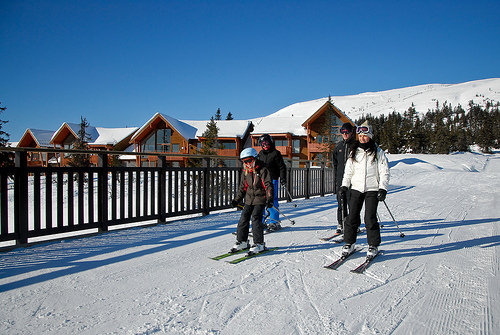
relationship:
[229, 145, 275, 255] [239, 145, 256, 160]
guy wearing blue helmet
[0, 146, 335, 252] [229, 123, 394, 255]
wooden fence beside skiers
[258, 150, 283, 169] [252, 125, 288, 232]
jacket on person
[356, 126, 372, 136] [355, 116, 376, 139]
goggles on hat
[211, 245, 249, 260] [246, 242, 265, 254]
green ski on foot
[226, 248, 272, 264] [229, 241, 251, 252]
green ski on foot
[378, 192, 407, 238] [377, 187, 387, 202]
pole in hand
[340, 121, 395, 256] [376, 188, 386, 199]
skiers wearing glove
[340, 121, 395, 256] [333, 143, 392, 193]
skiers wearing jacket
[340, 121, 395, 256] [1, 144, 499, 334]
skiers skating on snow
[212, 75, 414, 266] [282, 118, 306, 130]
roof covered with snow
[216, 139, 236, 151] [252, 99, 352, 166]
window of house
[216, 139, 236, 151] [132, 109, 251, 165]
window of house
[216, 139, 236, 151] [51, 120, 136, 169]
window of house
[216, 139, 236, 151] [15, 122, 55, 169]
window of house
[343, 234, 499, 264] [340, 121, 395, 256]
shadow of skiers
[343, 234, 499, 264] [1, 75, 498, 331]
shadow falling on snow